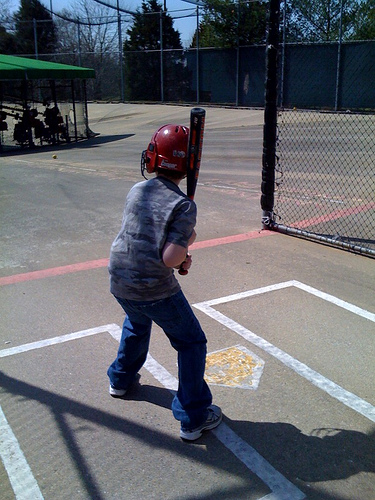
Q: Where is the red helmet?
A: On head.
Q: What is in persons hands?
A: A bat.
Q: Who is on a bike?
A: No one.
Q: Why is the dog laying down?
A: There is no dog.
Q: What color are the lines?
A: White and red.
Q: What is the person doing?
A: Batting.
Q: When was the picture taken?
A: Daytime.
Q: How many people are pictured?
A: One.